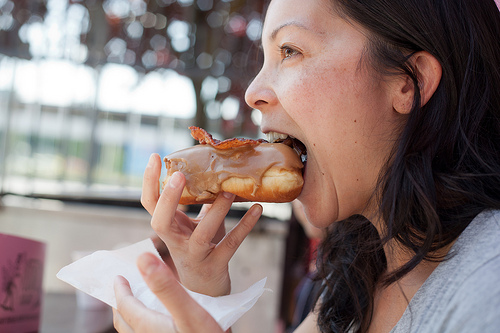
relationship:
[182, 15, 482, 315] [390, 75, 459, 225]
person with hair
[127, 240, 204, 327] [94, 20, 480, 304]
thumb of person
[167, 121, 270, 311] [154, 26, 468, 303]
fingers of person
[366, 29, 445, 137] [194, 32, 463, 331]
ear of person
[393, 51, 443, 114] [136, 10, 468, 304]
ear of person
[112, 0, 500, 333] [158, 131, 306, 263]
person holding donut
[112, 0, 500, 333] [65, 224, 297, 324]
person holding napkin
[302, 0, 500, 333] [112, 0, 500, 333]
hair belonging to person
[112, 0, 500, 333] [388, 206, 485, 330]
person wearing shirt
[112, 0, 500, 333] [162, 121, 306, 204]
person eating donut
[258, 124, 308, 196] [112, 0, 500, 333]
mouth belonging to person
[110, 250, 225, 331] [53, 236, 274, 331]
hand holding napkin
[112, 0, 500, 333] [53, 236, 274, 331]
person holding napkin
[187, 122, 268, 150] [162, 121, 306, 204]
chip topping donut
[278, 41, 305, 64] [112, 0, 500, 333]
left eye belonging to person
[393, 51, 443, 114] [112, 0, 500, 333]
ear belonging to person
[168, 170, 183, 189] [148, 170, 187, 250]
nail growing on finger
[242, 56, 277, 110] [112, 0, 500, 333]
nose belonging to person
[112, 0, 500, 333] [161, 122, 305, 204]
person eating doughnut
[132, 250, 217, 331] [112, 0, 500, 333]
thumb belonging to person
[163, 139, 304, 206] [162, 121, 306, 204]
chocolate covering donut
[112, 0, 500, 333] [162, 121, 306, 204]
person biting into donut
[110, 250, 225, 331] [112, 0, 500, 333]
hand belonging to person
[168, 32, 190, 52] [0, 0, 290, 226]
light lit up in distance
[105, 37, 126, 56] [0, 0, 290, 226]
light lit up in distance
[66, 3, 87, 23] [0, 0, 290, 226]
light lit up in distance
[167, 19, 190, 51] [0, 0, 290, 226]
light lit up in distance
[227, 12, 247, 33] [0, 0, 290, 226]
light lit up in distance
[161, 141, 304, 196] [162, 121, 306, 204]
chocolate covering donut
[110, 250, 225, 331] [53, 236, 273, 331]
hand holding paper